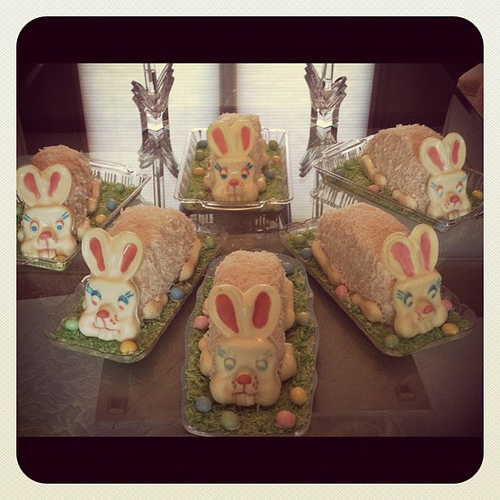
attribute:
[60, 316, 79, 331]
green egg — chocolate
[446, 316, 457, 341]
egg — yellow, chocolate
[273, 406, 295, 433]
egg — pink chocolate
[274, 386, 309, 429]
egg — chocolate, blue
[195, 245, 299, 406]
cake — rabbit shaped